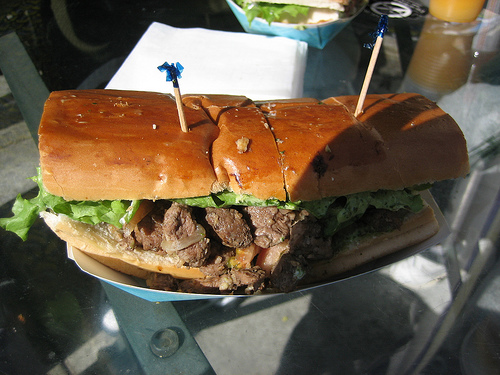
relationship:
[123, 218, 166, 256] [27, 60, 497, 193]
meat on bun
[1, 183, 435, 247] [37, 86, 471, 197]
lettuce on bun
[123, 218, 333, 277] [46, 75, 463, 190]
meat on bun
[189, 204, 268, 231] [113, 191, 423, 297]
beef on sandwich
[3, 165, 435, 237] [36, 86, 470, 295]
lettuce on food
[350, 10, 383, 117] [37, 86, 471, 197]
toothpic on bun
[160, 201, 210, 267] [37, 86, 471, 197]
meat on bun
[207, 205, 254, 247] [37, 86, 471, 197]
meat on bun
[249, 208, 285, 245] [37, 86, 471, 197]
beef on bun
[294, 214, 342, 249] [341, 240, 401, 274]
meat on bun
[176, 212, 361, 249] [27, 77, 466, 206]
meat on bun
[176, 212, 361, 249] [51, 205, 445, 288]
meat on bun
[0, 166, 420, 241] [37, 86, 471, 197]
lettuce on bun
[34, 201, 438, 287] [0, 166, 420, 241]
bun on lettuce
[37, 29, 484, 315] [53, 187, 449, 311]
food on basket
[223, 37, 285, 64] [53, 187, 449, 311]
napkins on basket